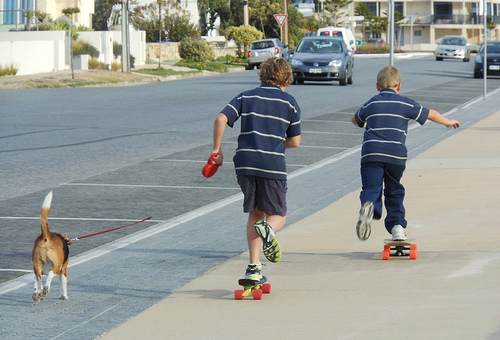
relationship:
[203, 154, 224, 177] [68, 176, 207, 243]
handle of leash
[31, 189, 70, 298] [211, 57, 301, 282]
dog alongside boy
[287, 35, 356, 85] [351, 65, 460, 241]
car driving toward boy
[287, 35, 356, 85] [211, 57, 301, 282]
car driving toward boy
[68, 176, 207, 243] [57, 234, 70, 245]
leash connecting to collar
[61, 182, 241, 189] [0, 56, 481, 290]
line on street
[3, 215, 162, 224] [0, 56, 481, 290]
line on street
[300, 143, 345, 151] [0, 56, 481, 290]
line on street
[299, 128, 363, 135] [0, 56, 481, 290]
line on street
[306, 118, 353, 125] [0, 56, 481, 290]
line on street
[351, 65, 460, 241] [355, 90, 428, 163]
boy wearing shirt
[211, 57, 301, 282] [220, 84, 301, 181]
boy wearing shirt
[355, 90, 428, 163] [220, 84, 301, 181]
shirt matches shirt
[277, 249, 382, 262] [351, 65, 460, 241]
shadow of boy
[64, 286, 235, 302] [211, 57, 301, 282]
shadow of boy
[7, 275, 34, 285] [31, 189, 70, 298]
shadow of dog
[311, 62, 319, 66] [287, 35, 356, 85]
logo on car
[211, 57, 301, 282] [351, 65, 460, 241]
boy behind boy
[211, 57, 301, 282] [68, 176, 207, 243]
boy holding leash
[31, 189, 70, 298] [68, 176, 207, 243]
dog on leash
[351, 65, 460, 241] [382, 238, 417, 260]
boy on skateboard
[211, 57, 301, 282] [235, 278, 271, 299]
boy on skateboard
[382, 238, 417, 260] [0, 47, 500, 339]
skateboard on street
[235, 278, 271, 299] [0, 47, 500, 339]
skateboard on street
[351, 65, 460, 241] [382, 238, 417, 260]
boy riding skateboard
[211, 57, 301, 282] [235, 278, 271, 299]
boy riding skateboard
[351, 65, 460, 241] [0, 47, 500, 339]
boy riding on street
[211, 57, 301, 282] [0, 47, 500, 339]
boy riding on street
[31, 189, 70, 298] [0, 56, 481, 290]
dog beside street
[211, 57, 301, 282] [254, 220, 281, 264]
boy wearing tennis shoe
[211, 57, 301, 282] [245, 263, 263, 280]
boy wearing tennis shoe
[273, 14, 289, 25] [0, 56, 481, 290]
sign next to street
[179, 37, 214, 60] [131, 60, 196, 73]
bush on sidewalk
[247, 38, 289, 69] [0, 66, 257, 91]
car next to curb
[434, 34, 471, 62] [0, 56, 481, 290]
car on street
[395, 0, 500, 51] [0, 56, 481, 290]
building near street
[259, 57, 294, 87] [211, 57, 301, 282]
hair on boy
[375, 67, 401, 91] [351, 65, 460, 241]
hair on boy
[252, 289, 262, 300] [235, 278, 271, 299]
wheel on skateboard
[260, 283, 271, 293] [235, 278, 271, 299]
wheel on skateboard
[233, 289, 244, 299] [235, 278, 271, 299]
wheel on skateboard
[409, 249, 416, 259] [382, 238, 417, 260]
wheel on skateboard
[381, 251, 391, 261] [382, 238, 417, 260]
wheel on skateboard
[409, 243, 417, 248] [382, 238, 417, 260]
wheel on skateboard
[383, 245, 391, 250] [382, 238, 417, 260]
wheel on skateboard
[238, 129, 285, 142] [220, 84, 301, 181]
stripe on shirt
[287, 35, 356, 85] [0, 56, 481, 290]
car on street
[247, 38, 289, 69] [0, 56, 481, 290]
car beside street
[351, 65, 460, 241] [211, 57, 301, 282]
boy in front of boy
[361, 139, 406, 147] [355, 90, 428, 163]
stripe on shirt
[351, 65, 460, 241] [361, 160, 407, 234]
boy wearing pants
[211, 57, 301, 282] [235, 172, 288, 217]
boy wearing shorts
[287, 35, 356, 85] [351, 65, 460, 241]
car opposite boy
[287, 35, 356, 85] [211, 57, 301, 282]
car opposite boy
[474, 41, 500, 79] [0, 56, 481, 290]
car on street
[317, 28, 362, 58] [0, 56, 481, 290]
van on street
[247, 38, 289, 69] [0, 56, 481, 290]
car on street